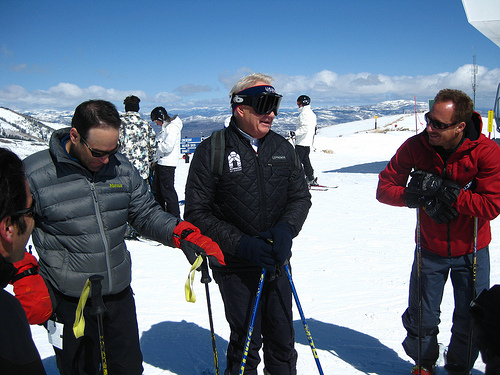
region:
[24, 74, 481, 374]
group of skiers talking on hill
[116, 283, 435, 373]
shadow's of skiers cast on snow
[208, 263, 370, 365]
blue ski poles in hand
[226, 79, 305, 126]
black ski goggles on skier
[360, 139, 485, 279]
red hoodie on skier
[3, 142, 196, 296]
gray jacket on skier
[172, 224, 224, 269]
red gloves on skier's hands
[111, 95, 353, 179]
skiers in background facing away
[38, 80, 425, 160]
snow covered mountains in the distance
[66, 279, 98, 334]
yellow loops on ski poles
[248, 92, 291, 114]
large goggles on the man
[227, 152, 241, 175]
a logo on man's jacket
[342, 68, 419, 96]
some clouds in the sky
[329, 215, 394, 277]
some snow on the slope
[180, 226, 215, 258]
red mitten on the man's hand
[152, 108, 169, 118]
black helmet on the person's head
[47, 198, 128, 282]
front part of man's jacket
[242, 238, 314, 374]
man in blue mittens holding ski poles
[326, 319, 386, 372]
a reflection of man in snow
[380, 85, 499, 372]
a man on the ski slope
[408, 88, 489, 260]
man wearing a red coat and black gloves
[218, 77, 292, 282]
man wearing black ski goggles and blue gloves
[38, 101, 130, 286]
man wearing sunglasses and a gray coat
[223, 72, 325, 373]
man holding blue ski poles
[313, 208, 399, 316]
snow on the ski mountain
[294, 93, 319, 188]
person on skis wearing a white coat and a black helmet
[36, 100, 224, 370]
man wearing red mittens and black ski pants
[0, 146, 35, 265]
side of a man's face with sunglasses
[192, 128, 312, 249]
black coat with a diamond pattern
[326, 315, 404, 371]
shadow being cast on the ground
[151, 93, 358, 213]
two people wearing white coats in background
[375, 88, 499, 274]
man wearing red coat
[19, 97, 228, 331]
man wearing grey coat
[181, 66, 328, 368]
man wearing black coat and pants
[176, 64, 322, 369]
man with grey hair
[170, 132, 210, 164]
blue sign in the background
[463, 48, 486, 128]
one leafless tree in background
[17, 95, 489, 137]
mountains in the distance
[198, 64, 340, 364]
man in black holding blue ski poles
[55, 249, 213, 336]
yellow wrist straps on black ski poles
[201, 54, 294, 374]
skier on the slope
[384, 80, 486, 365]
skier on the slope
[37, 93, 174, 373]
skier on the slope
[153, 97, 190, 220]
skier on the slope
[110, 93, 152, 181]
skier on the slope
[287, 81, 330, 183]
skier on the slope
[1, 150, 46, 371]
skier on the slope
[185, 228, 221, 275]
glove on the skier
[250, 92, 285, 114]
goggles on the skier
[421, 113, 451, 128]
sunglasses on the skier